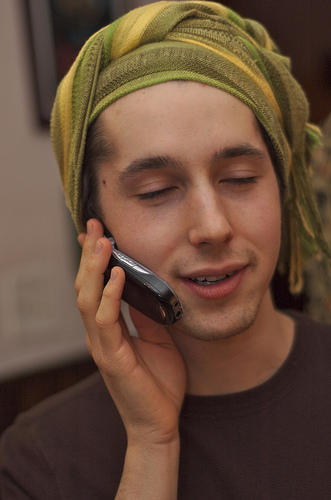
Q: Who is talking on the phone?
A: The man.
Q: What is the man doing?
A: Talking on the phone.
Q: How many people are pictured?
A: One.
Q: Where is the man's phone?
A: In his hand.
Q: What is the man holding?
A: His phone.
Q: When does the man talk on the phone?
A: Now.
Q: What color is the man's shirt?
A: Brown.